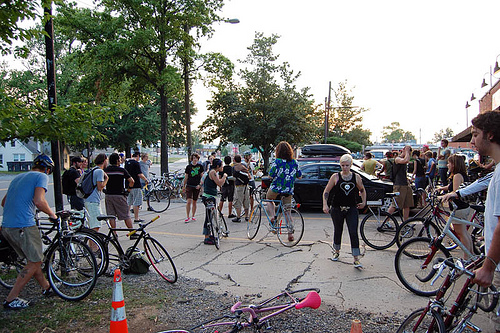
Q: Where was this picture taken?
A: A neighborhood.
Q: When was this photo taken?
A: During daylight.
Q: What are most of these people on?
A: Bikes.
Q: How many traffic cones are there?
A: 1.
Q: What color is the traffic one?
A: White and Orange.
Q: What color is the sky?
A: White.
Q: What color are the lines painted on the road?
A: White and Yellow.